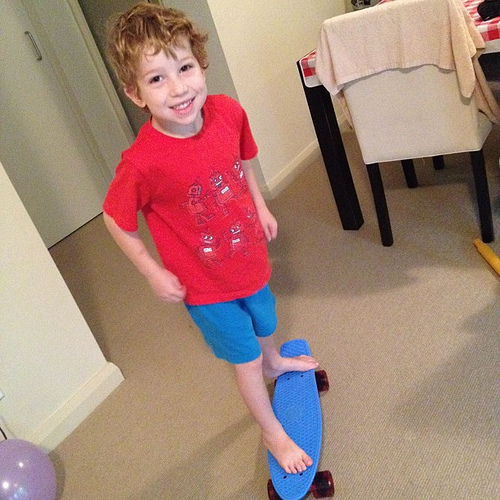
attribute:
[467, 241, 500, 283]
toy — yellow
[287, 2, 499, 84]
cloth — red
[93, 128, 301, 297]
shirt — red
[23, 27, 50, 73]
handle — grey, metal, long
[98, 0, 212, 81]
hair — blonde, wavy, messy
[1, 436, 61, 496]
ball — purple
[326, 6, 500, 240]
chair — black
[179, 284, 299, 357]
shorts — blue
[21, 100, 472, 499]
floor — grey, white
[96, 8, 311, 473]
boy — little, white, happy, smiling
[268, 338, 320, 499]
skateboard — blue, toy, small, plastic